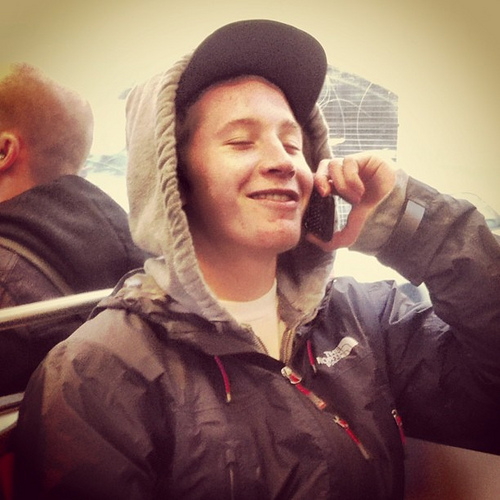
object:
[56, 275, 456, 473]
jacket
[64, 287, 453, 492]
jacket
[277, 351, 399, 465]
zippers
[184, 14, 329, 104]
cap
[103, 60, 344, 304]
hood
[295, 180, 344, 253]
phone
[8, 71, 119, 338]
man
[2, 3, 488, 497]
picture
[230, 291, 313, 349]
shirt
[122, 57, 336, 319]
hoodie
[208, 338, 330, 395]
ties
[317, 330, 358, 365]
logo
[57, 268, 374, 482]
jacket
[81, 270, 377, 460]
jacket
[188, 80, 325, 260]
man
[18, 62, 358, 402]
people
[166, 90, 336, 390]
person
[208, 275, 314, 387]
shirt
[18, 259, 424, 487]
breaker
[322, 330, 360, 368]
logo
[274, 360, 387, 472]
zipper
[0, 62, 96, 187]
head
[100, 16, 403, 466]
man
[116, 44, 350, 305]
hoodie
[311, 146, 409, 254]
hand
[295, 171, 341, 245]
phone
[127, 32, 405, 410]
man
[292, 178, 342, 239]
phone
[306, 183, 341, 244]
phone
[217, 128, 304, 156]
eyes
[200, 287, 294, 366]
shirt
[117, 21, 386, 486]
man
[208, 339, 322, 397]
strings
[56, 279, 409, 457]
jacket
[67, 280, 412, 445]
jacket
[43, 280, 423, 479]
jacket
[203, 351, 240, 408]
string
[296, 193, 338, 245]
phone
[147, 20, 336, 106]
hat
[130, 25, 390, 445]
man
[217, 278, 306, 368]
shirt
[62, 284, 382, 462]
jacket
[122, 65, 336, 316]
hood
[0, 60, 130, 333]
guy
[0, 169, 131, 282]
hood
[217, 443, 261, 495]
zipper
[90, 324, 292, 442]
jacket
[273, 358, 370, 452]
zipper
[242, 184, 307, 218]
grin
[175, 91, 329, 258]
face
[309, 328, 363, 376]
logo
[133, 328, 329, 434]
jacket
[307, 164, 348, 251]
cell phone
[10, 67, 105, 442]
man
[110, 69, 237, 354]
hoodie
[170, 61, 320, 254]
head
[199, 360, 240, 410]
tie pull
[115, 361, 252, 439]
jacket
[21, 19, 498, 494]
boy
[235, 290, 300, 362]
t-shirt